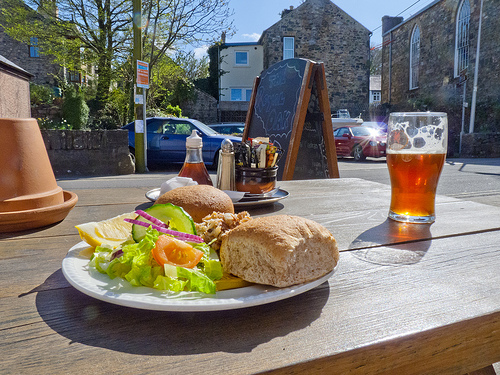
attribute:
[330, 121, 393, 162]
car — red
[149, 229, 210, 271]
tomato — red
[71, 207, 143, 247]
lemon — wedge 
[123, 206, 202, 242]
purple onion — puple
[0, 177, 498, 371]
table — tan  , wooden 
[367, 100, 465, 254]
glass —  clear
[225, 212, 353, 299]
roll — bread, light brown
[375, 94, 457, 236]
glass —  two thirds full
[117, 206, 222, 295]
salad — Mixed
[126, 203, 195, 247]
cucumber — green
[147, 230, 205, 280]
tomato — yellow, wedge 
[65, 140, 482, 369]
table — brown, wooden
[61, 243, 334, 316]
plate — round, white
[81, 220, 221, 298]
lettuce — Chopped 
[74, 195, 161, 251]
lemon — yellow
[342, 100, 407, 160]
sun — glaring off 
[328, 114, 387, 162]
car —  red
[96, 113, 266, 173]
car — blue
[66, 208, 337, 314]
plate — white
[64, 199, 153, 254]
wedge — lemon